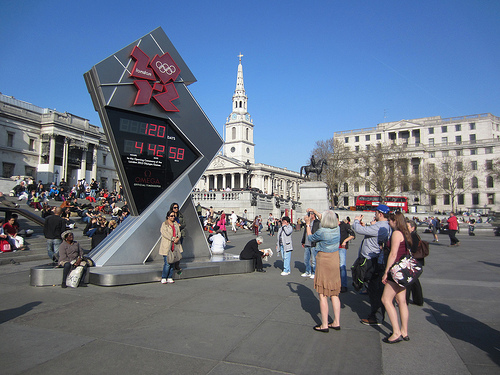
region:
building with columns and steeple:
[211, 51, 301, 197]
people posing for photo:
[161, 202, 185, 283]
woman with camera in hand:
[305, 209, 342, 330]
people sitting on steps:
[0, 181, 123, 266]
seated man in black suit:
[240, 235, 272, 273]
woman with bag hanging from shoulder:
[379, 209, 421, 344]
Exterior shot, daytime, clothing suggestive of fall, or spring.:
[5, 3, 498, 373]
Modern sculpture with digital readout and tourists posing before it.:
[86, 47, 240, 283]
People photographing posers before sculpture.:
[307, 200, 391, 332]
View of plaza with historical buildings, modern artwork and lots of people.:
[2, 40, 499, 373]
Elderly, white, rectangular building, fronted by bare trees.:
[332, 117, 499, 222]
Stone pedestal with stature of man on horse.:
[297, 152, 331, 214]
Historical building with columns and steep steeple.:
[204, 54, 305, 194]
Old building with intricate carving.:
[2, 101, 124, 179]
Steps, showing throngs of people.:
[0, 165, 125, 226]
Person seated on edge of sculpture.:
[38, 229, 91, 294]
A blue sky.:
[0, 0, 497, 168]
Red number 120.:
[142, 121, 167, 138]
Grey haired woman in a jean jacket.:
[302, 209, 341, 332]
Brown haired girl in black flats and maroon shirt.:
[378, 212, 412, 344]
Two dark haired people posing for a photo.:
[158, 202, 185, 284]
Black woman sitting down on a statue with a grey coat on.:
[55, 228, 85, 290]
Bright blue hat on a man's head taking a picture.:
[375, 201, 390, 215]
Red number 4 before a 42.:
[133, 137, 143, 155]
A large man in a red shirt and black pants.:
[445, 211, 459, 246]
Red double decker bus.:
[355, 192, 408, 214]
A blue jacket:
[303, 224, 344, 253]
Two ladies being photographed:
[155, 200, 200, 287]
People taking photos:
[287, 194, 394, 336]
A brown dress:
[315, 247, 345, 302]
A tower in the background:
[220, 41, 257, 158]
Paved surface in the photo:
[131, 308, 248, 352]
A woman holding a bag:
[371, 208, 428, 352]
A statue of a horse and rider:
[298, 157, 334, 184]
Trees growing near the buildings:
[325, 139, 420, 191]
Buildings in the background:
[342, 124, 492, 216]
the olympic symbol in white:
[156, 62, 177, 76]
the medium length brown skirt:
[313, 251, 342, 298]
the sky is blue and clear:
[0, 0, 498, 175]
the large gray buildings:
[0, 93, 498, 217]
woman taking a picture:
[302, 207, 342, 332]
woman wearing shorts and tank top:
[381, 207, 410, 342]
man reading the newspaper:
[239, 235, 273, 274]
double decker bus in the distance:
[353, 192, 409, 212]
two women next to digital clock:
[158, 202, 188, 284]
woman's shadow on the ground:
[287, 279, 333, 324]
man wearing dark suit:
[239, 236, 269, 272]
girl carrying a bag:
[378, 211, 420, 343]